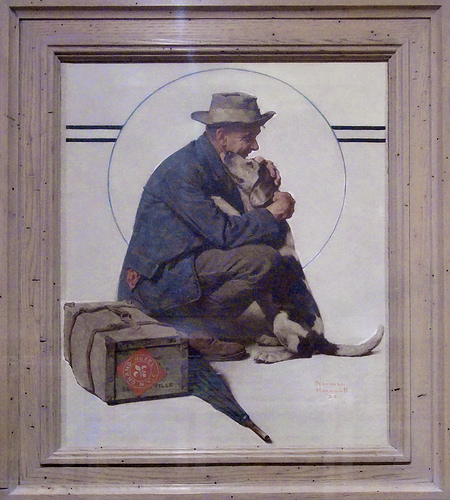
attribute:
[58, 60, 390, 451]
picture — white, norman rockwell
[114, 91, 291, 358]
man — older, sitting, squatting, elderly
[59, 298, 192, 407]
case — edged, wood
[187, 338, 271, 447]
umbrella — tipped, long, blue, metalic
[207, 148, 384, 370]
dog — spotted, black, short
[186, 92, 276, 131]
hat — beat-up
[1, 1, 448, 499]
frame — wooden, light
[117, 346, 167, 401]
sticker — orange, red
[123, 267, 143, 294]
rag — red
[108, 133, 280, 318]
jacket — blue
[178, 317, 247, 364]
boot — worn, brown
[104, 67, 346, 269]
circle — blue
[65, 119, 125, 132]
stripe — black